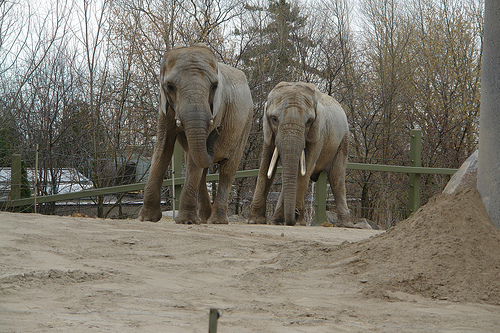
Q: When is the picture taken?
A: Daytime.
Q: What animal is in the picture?
A: Elephants.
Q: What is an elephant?
A: A mammal.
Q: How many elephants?
A: Two.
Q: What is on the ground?
A: Dirt.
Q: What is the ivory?
A: Tusk.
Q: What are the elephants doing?
A: Standing.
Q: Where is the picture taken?
A: Near elephants.